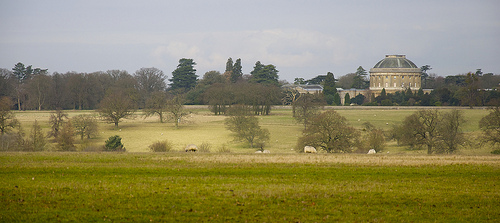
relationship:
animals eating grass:
[366, 147, 379, 156] [1, 145, 499, 219]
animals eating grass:
[302, 142, 318, 155] [1, 145, 499, 219]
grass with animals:
[1, 145, 499, 219] [366, 147, 379, 156]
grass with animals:
[1, 145, 499, 219] [302, 142, 318, 155]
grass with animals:
[1, 145, 499, 219] [183, 147, 202, 154]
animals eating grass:
[183, 147, 202, 154] [1, 145, 499, 219]